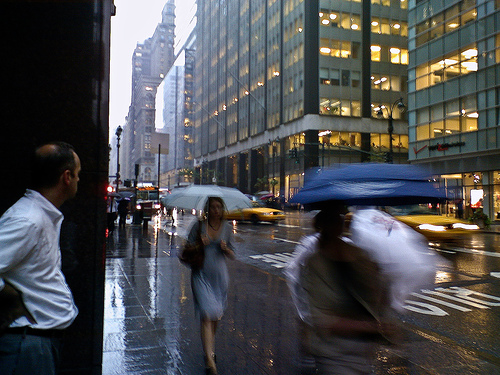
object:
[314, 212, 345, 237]
head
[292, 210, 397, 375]
person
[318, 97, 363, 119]
window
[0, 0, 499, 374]
building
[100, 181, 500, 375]
street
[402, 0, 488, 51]
window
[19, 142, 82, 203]
head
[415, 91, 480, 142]
window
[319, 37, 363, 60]
window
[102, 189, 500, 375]
ground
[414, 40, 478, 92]
glass window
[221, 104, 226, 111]
window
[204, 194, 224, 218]
head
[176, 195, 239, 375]
person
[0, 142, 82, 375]
person